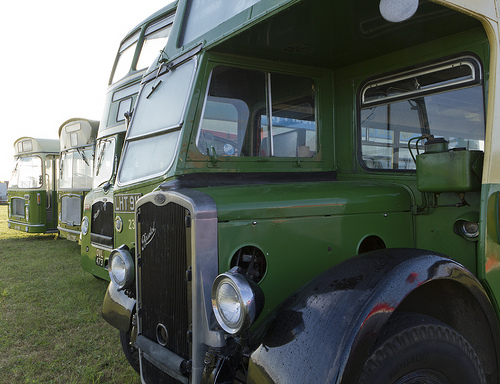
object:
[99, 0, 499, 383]
bus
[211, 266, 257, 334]
light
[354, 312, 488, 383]
tire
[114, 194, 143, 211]
plate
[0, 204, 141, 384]
grass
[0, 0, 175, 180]
sky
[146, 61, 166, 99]
wiper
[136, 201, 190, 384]
grill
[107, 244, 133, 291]
light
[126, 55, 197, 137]
windshield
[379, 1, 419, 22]
mirror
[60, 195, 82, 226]
grill